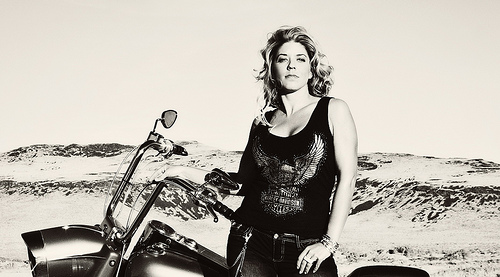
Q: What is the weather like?
A: It is clear.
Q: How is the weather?
A: It is clear.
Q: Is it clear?
A: Yes, it is clear.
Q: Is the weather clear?
A: Yes, it is clear.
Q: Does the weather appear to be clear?
A: Yes, it is clear.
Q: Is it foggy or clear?
A: It is clear.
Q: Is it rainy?
A: No, it is clear.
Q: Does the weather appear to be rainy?
A: No, it is clear.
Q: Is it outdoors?
A: Yes, it is outdoors.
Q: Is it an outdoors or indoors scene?
A: It is outdoors.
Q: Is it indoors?
A: No, it is outdoors.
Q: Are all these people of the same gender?
A: Yes, all the people are female.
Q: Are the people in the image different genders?
A: No, all the people are female.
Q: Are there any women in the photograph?
A: Yes, there is a woman.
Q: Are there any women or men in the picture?
A: Yes, there is a woman.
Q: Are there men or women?
A: Yes, there is a woman.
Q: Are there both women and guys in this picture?
A: No, there is a woman but no guys.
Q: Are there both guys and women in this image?
A: No, there is a woman but no guys.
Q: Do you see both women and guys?
A: No, there is a woman but no guys.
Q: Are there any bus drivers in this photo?
A: No, there are no bus drivers.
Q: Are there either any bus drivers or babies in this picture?
A: No, there are no bus drivers or babies.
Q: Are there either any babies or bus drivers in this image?
A: No, there are no bus drivers or babies.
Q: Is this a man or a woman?
A: This is a woman.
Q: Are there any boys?
A: No, there are no boys.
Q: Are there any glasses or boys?
A: No, there are no boys or glasses.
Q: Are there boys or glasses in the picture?
A: No, there are no boys or glasses.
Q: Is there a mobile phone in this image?
A: No, there are no cell phones.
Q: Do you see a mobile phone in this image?
A: No, there are no cell phones.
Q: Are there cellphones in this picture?
A: No, there are no cellphones.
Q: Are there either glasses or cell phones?
A: No, there are no cell phones or glasses.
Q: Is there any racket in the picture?
A: No, there are no rackets.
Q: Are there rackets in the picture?
A: No, there are no rackets.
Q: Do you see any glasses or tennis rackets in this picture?
A: No, there are no tennis rackets or glasses.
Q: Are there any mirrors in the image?
A: Yes, there is a mirror.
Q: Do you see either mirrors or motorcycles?
A: Yes, there is a mirror.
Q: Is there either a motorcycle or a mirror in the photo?
A: Yes, there is a mirror.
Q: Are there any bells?
A: No, there are no bells.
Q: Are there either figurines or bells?
A: No, there are no bells or figurines.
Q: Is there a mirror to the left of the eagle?
A: Yes, there is a mirror to the left of the eagle.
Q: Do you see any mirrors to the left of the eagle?
A: Yes, there is a mirror to the left of the eagle.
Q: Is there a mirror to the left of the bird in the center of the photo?
A: Yes, there is a mirror to the left of the eagle.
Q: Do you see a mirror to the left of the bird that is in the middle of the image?
A: Yes, there is a mirror to the left of the eagle.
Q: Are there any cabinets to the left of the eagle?
A: No, there is a mirror to the left of the eagle.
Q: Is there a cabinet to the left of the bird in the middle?
A: No, there is a mirror to the left of the eagle.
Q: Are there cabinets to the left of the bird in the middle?
A: No, there is a mirror to the left of the eagle.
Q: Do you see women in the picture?
A: Yes, there is a woman.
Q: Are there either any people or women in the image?
A: Yes, there is a woman.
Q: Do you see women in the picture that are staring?
A: Yes, there is a woman that is staring.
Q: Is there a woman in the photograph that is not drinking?
A: Yes, there is a woman that is staring.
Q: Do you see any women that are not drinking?
A: Yes, there is a woman that is staring .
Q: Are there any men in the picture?
A: No, there are no men.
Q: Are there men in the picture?
A: No, there are no men.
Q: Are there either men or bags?
A: No, there are no men or bags.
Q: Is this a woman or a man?
A: This is a woman.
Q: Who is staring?
A: The woman is staring.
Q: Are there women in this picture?
A: Yes, there is a woman.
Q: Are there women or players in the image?
A: Yes, there is a woman.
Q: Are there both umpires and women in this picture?
A: No, there is a woman but no umpires.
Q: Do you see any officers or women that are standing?
A: Yes, the woman is standing.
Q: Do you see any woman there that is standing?
A: Yes, there is a woman that is standing.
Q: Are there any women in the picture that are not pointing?
A: Yes, there is a woman that is standing.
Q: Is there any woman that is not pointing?
A: Yes, there is a woman that is standing.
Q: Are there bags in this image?
A: No, there are no bags.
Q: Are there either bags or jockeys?
A: No, there are no bags or jockeys.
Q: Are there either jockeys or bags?
A: No, there are no bags or jockeys.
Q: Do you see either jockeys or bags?
A: No, there are no bags or jockeys.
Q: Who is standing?
A: The woman is standing.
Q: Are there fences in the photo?
A: No, there are no fences.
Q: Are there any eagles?
A: Yes, there is an eagle.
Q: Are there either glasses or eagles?
A: Yes, there is an eagle.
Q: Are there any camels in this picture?
A: No, there are no camels.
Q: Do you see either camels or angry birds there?
A: No, there are no camels or angry birds.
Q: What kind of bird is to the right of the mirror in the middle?
A: The bird is an eagle.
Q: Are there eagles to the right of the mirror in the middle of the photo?
A: Yes, there is an eagle to the right of the mirror.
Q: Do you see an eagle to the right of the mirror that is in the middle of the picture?
A: Yes, there is an eagle to the right of the mirror.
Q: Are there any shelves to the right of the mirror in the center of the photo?
A: No, there is an eagle to the right of the mirror.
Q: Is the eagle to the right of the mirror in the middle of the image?
A: Yes, the eagle is to the right of the mirror.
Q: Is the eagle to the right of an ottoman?
A: No, the eagle is to the right of the mirror.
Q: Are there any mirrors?
A: Yes, there is a mirror.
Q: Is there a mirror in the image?
A: Yes, there is a mirror.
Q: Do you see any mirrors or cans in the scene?
A: Yes, there is a mirror.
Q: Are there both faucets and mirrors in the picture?
A: No, there is a mirror but no faucets.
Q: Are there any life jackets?
A: No, there are no life jackets.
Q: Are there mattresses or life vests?
A: No, there are no life vests or mattresses.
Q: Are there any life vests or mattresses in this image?
A: No, there are no life vests or mattresses.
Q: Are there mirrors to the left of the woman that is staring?
A: Yes, there is a mirror to the left of the woman.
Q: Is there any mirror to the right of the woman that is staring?
A: No, the mirror is to the left of the woman.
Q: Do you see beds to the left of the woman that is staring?
A: No, there is a mirror to the left of the woman.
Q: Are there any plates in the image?
A: No, there are no plates.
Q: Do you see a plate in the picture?
A: No, there are no plates.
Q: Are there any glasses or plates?
A: No, there are no plates or glasses.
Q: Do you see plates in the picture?
A: No, there are no plates.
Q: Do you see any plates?
A: No, there are no plates.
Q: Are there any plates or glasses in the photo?
A: No, there are no plates or glasses.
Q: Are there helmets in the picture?
A: No, there are no helmets.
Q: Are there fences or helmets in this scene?
A: No, there are no helmets or fences.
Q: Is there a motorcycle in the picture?
A: Yes, there is a motorcycle.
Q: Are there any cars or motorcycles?
A: Yes, there is a motorcycle.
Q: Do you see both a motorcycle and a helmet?
A: No, there is a motorcycle but no helmets.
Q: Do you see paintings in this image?
A: No, there are no paintings.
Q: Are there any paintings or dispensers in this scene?
A: No, there are no paintings or dispensers.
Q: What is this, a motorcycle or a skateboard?
A: This is a motorcycle.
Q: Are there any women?
A: Yes, there is a woman.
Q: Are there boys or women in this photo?
A: Yes, there is a woman.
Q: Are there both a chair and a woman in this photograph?
A: No, there is a woman but no chairs.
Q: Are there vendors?
A: No, there are no vendors.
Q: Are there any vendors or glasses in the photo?
A: No, there are no vendors or glasses.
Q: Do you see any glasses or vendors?
A: No, there are no vendors or glasses.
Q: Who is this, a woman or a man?
A: This is a woman.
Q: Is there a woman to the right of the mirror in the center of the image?
A: Yes, there is a woman to the right of the mirror.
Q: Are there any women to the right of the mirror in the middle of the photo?
A: Yes, there is a woman to the right of the mirror.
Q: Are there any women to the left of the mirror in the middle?
A: No, the woman is to the right of the mirror.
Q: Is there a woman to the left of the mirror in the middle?
A: No, the woman is to the right of the mirror.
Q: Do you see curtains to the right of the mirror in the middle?
A: No, there is a woman to the right of the mirror.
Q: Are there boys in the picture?
A: No, there are no boys.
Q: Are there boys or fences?
A: No, there are no boys or fences.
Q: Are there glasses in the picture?
A: No, there are no glasses.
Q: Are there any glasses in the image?
A: No, there are no glasses.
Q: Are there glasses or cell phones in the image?
A: No, there are no glasses or cell phones.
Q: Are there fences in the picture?
A: No, there are no fences.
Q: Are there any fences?
A: No, there are no fences.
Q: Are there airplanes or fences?
A: No, there are no fences or airplanes.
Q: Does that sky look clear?
A: Yes, the sky is clear.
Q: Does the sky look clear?
A: Yes, the sky is clear.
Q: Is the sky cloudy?
A: No, the sky is clear.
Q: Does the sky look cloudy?
A: No, the sky is clear.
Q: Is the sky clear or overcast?
A: The sky is clear.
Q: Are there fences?
A: No, there are no fences.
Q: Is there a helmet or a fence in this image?
A: No, there are no fences or helmets.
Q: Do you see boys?
A: No, there are no boys.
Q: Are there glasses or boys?
A: No, there are no boys or glasses.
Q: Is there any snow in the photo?
A: Yes, there is snow.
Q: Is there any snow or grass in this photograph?
A: Yes, there is snow.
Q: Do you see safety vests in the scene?
A: No, there are no safety vests.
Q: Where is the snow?
A: The snow is on the hill.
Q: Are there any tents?
A: No, there are no tents.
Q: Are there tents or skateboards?
A: No, there are no tents or skateboards.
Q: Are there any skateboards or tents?
A: No, there are no tents or skateboards.